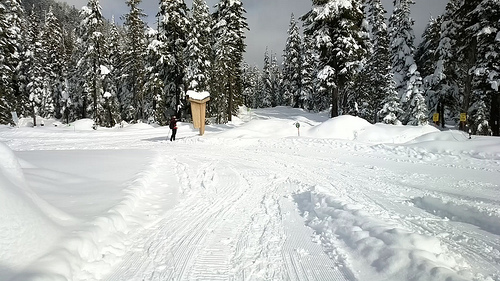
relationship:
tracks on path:
[119, 161, 317, 279] [101, 144, 495, 279]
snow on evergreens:
[5, 5, 240, 123] [152, 81, 190, 145]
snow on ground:
[2, 104, 497, 279] [0, 106, 498, 279]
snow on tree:
[380, 17, 431, 124] [380, 8, 460, 140]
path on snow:
[101, 138, 499, 280] [2, 104, 497, 279]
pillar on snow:
[431, 102, 441, 125] [2, 104, 497, 279]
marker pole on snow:
[294, 120, 301, 137] [2, 104, 497, 279]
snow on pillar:
[60, 143, 475, 265] [187, 87, 209, 134]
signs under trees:
[421, 86, 483, 128] [311, 17, 463, 102]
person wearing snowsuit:
[160, 87, 184, 147] [166, 116, 179, 142]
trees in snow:
[2, 1, 499, 137] [2, 104, 497, 279]